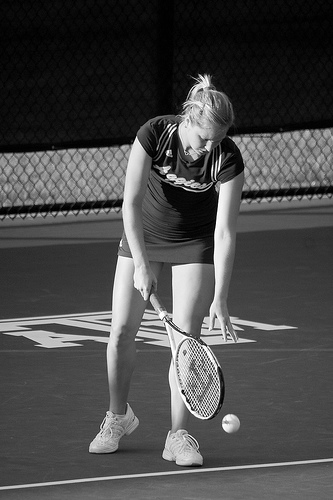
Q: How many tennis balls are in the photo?
A: One.